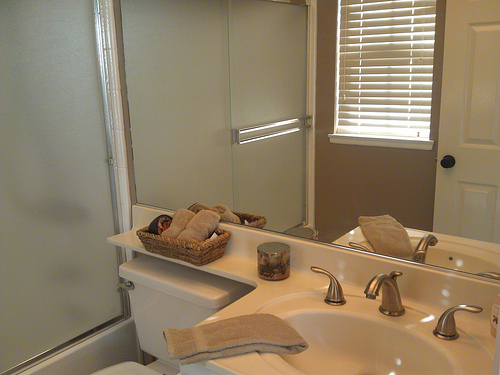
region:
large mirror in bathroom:
[104, 0, 499, 280]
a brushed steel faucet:
[363, 271, 408, 317]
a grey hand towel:
[159, 307, 311, 362]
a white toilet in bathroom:
[80, 253, 247, 373]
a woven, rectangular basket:
[135, 221, 232, 266]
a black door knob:
[439, 154, 455, 170]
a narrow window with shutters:
[324, 1, 435, 151]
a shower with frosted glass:
[0, 1, 127, 374]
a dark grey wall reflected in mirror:
[347, 156, 381, 192]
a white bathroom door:
[430, 0, 498, 242]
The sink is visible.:
[255, 218, 442, 373]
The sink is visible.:
[262, 268, 337, 338]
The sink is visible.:
[207, 255, 378, 357]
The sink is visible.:
[248, 294, 333, 369]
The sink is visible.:
[295, 270, 415, 357]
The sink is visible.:
[292, 330, 337, 362]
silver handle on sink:
[304, 261, 340, 307]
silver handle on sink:
[431, 295, 477, 347]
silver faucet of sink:
[363, 265, 408, 319]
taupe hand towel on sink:
[144, 305, 308, 362]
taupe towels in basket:
[165, 210, 207, 242]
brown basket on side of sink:
[133, 210, 217, 269]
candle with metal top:
[253, 236, 288, 286]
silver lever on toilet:
[114, 279, 137, 297]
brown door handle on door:
[433, 150, 455, 171]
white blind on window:
[338, 0, 431, 140]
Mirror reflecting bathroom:
[80, 2, 492, 308]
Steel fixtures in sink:
[294, 248, 487, 353]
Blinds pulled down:
[324, 3, 441, 157]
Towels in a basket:
[112, 191, 268, 273]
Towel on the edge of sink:
[151, 297, 358, 374]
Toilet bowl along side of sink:
[79, 236, 234, 373]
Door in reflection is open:
[423, 6, 497, 251]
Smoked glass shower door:
[121, 8, 306, 242]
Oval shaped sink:
[238, 282, 462, 374]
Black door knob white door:
[417, 128, 485, 224]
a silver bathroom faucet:
[272, 222, 497, 345]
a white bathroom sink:
[207, 220, 477, 372]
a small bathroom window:
[307, 2, 461, 185]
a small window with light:
[322, 16, 440, 176]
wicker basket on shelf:
[122, 182, 257, 286]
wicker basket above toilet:
[107, 181, 251, 281]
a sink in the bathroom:
[189, 210, 498, 373]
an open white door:
[423, 4, 499, 239]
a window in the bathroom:
[316, 2, 471, 187]